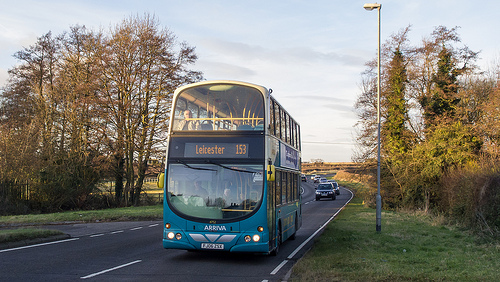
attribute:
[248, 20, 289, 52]
sky — blue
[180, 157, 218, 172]
wiper — black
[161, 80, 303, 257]
blue bus — double deck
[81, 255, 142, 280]
line — white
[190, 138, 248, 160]
bus sign — lighted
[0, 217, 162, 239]
road — off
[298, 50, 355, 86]
clouds — white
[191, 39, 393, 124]
clouds — white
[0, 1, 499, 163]
sky — blue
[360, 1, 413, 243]
post — grey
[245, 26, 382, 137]
clouds — white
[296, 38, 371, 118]
clouds — white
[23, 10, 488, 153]
sky — blue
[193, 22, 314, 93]
cloud — white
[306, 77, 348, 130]
cloud — white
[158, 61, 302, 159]
level — upper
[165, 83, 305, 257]
bus — blue, double decker